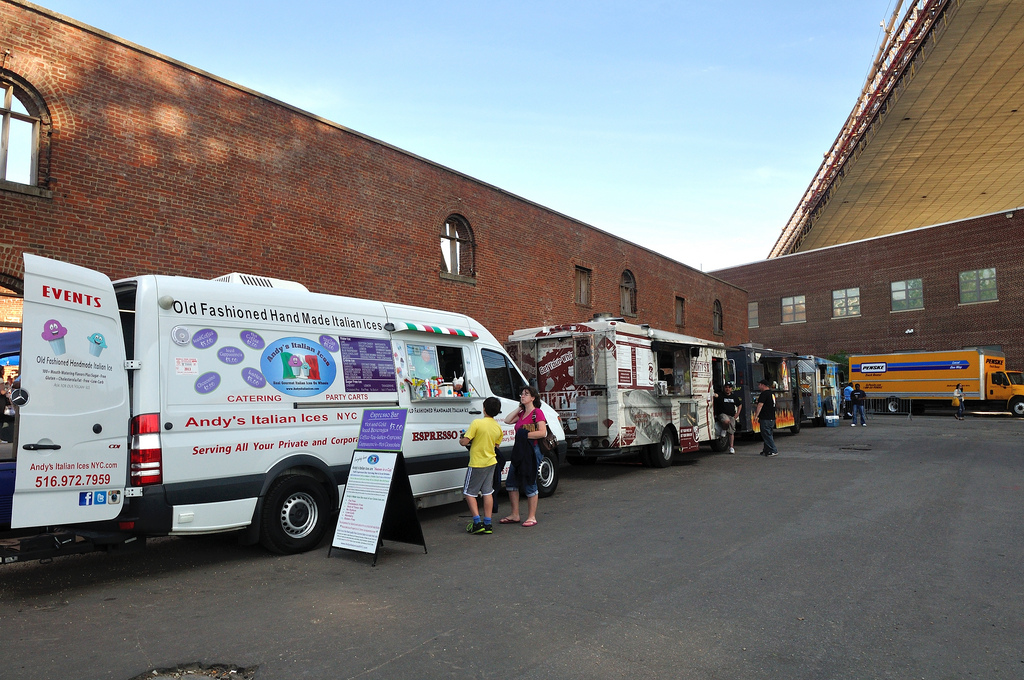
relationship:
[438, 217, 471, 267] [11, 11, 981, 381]
window on building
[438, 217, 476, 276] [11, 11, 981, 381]
window on building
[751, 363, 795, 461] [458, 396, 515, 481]
boy in shirt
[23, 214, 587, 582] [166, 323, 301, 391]
truck with flames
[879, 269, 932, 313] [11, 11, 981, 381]
window on building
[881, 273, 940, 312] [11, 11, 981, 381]
window on building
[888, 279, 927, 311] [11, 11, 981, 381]
window on building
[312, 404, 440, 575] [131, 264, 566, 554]
board in front of van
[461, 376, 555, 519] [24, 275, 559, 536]
people are in front of truck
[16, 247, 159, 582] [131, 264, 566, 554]
door attached to van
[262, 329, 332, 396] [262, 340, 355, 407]
faces are attached to ices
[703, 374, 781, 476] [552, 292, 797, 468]
person leaning on truck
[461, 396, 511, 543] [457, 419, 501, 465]
boy wearing shirt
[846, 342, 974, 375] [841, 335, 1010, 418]
stripe attached to truck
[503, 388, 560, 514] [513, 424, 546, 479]
woman wearing jacket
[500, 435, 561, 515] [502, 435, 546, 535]
woman wearing pants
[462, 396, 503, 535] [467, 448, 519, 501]
boy wearing shorts